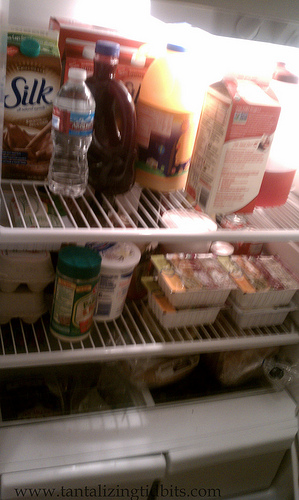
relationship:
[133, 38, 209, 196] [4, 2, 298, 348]
juice in fridge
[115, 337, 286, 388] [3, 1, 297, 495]
bread in fridge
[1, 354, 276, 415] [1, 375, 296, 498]
shelf in fridge bottom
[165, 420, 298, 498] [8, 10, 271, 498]
carton in fridge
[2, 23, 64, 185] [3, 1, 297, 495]
carton in fridge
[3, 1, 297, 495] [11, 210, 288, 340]
fridge for food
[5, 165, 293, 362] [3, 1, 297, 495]
bar in fridge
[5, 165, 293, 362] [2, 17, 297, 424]
bar for food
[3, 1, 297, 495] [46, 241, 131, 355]
fridge full of food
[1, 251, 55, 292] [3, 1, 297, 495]
eggs in fridge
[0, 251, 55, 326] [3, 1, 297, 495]
eggs in fridge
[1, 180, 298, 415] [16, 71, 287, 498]
shelf in fridge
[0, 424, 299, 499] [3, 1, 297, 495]
drawers in fridge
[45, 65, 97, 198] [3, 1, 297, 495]
bottle in fridge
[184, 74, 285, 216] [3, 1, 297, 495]
carton in fridge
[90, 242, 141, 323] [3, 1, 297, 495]
yogurt in fridge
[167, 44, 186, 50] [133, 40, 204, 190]
cap on bottle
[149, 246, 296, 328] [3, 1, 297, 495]
food in fridge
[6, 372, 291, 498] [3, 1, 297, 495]
drawers in fridge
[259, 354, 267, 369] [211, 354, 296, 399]
tie on plastic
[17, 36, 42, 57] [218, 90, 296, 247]
cap on milk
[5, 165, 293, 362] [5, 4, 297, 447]
bar in fridge